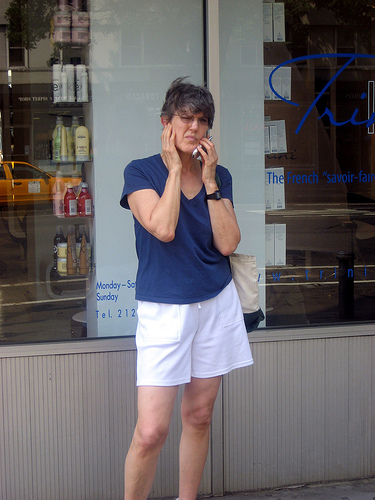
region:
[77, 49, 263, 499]
this is a woman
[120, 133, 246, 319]
woman wearing purple shirt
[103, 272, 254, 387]
woman wearing white shorts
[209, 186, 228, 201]
woman wearing black watch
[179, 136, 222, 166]
cell phone is silver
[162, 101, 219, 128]
woman wearing pair of glasses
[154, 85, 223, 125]
woman has dark hair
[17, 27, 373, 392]
woman standing in front of window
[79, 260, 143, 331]
blue writing on window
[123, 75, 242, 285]
woman on a cell phone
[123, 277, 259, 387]
white shorts on the woman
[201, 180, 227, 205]
watch on woman's wrist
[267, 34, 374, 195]
blue writing on a window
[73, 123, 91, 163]
bottle in a store window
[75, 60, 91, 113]
white bottles in a store window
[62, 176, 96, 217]
bottles in a store window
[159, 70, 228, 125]
The woman has dark hair.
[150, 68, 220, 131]
The woman's hair is short.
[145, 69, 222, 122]
The woman's hair is black.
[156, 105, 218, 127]
The woman is wearing glasses.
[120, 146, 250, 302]
The woman is wearing a blue shirt.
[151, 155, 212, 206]
The shirt has a V neck.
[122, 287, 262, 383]
The woman is wearing white shorts.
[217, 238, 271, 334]
The woman is carrying a purse.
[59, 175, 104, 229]
The red bottles are displayed in the window.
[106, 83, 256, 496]
this is a lady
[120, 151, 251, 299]
this is a blue shirt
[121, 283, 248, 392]
these are white shorts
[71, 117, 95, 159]
this is a bottle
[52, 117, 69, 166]
this is a bottle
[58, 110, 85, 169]
this is a bottle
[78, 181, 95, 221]
this is a bottle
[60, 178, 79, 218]
this is a bottle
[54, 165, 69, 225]
this is a bottle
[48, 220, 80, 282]
this is a bottle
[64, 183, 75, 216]
short red bottle with white label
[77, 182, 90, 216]
short red bottle with white cap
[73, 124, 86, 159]
plastic yellow bottle with silver cap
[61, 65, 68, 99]
white plastic spray bottle with gray top